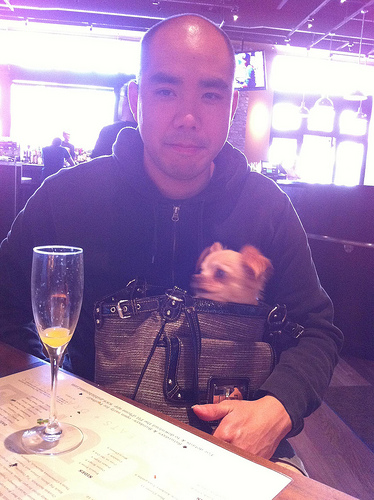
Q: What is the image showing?
A: It is showing a restaurant.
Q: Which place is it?
A: It is a restaurant.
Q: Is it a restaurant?
A: Yes, it is a restaurant.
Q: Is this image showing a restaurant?
A: Yes, it is showing a restaurant.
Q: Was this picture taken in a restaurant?
A: Yes, it was taken in a restaurant.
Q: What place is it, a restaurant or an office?
A: It is a restaurant.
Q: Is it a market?
A: No, it is a restaurant.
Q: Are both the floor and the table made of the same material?
A: Yes, both the floor and the table are made of wood.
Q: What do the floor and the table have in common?
A: The material, both the floor and the table are wooden.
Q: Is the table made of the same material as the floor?
A: Yes, both the table and the floor are made of wood.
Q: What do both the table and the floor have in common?
A: The material, both the table and the floor are wooden.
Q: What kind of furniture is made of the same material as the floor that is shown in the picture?
A: The table is made of the same material as the floor.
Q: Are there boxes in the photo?
A: No, there are no boxes.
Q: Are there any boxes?
A: No, there are no boxes.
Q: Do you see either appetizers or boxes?
A: No, there are no boxes or appetizers.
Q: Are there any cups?
A: No, there are no cups.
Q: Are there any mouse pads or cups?
A: No, there are no cups or mouse pads.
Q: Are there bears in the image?
A: No, there are no bears.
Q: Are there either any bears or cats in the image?
A: No, there are no bears or cats.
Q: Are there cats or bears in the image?
A: No, there are no bears or cats.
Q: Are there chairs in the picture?
A: No, there are no chairs.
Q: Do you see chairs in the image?
A: No, there are no chairs.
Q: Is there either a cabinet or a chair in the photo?
A: No, there are no chairs or cabinets.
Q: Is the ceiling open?
A: Yes, the ceiling is open.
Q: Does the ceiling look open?
A: Yes, the ceiling is open.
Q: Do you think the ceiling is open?
A: Yes, the ceiling is open.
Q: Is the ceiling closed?
A: No, the ceiling is open.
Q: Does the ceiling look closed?
A: No, the ceiling is open.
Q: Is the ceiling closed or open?
A: The ceiling is open.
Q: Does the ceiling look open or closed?
A: The ceiling is open.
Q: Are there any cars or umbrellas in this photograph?
A: No, there are no umbrellas or cars.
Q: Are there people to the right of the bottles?
A: Yes, there are people to the right of the bottles.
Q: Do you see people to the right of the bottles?
A: Yes, there are people to the right of the bottles.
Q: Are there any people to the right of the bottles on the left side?
A: Yes, there are people to the right of the bottles.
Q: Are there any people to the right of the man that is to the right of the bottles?
A: Yes, there are people to the right of the man.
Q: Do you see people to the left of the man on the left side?
A: No, the people are to the right of the man.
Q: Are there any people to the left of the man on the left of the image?
A: No, the people are to the right of the man.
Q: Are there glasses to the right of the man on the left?
A: No, there are people to the right of the man.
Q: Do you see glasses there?
A: No, there are no glasses.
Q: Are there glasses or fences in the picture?
A: No, there are no glasses or fences.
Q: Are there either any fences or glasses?
A: No, there are no glasses or fences.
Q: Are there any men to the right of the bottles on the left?
A: Yes, there is a man to the right of the bottles.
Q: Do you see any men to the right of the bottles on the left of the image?
A: Yes, there is a man to the right of the bottles.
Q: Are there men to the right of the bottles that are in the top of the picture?
A: Yes, there is a man to the right of the bottles.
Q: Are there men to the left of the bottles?
A: No, the man is to the right of the bottles.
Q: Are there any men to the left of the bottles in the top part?
A: No, the man is to the right of the bottles.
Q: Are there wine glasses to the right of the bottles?
A: No, there is a man to the right of the bottles.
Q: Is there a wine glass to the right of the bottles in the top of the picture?
A: No, there is a man to the right of the bottles.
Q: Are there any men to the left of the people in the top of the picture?
A: Yes, there is a man to the left of the people.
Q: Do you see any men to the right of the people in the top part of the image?
A: No, the man is to the left of the people.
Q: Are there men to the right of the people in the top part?
A: No, the man is to the left of the people.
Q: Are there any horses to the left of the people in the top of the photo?
A: No, there is a man to the left of the people.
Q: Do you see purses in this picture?
A: Yes, there is a purse.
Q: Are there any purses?
A: Yes, there is a purse.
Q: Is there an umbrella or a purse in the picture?
A: Yes, there is a purse.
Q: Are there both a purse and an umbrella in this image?
A: No, there is a purse but no umbrellas.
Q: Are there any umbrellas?
A: No, there are no umbrellas.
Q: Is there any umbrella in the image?
A: No, there are no umbrellas.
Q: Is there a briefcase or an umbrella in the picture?
A: No, there are no umbrellas or briefcases.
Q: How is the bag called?
A: The bag is a purse.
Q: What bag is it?
A: The bag is a purse.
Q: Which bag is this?
A: That is a purse.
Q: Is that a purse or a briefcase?
A: That is a purse.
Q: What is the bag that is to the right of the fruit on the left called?
A: The bag is a purse.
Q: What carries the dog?
A: The purse carries the dog.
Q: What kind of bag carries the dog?
A: The bag is a purse.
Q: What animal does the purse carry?
A: The purse carries a dog.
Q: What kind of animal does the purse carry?
A: The purse carries a dog.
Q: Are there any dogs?
A: Yes, there is a dog.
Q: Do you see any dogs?
A: Yes, there is a dog.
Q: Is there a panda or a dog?
A: Yes, there is a dog.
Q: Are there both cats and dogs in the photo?
A: No, there is a dog but no cats.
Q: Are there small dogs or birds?
A: Yes, there is a small dog.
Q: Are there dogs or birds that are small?
A: Yes, the dog is small.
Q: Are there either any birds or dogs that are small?
A: Yes, the dog is small.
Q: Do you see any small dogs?
A: Yes, there is a small dog.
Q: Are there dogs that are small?
A: Yes, there is a dog that is small.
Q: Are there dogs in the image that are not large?
A: Yes, there is a small dog.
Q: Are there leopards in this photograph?
A: No, there are no leopards.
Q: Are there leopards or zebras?
A: No, there are no leopards or zebras.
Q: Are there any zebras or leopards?
A: No, there are no leopards or zebras.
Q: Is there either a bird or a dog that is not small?
A: No, there is a dog but it is small.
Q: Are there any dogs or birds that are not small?
A: No, there is a dog but it is small.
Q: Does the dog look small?
A: Yes, the dog is small.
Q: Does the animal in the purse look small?
A: Yes, the dog is small.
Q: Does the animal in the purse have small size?
A: Yes, the dog is small.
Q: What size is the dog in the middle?
A: The dog is small.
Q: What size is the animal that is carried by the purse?
A: The dog is small.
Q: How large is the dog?
A: The dog is small.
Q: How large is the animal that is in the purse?
A: The dog is small.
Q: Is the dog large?
A: No, the dog is small.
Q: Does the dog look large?
A: No, the dog is small.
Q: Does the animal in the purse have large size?
A: No, the dog is small.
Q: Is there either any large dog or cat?
A: No, there is a dog but it is small.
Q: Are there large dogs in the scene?
A: No, there is a dog but it is small.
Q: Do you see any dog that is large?
A: No, there is a dog but it is small.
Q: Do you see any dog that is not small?
A: No, there is a dog but it is small.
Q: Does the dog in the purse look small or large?
A: The dog is small.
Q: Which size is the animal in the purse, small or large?
A: The dog is small.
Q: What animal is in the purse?
A: The dog is in the purse.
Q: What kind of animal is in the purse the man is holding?
A: The animal is a dog.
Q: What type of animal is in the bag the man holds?
A: The animal is a dog.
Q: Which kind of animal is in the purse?
A: The animal is a dog.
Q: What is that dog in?
A: The dog is in the purse.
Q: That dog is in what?
A: The dog is in the purse.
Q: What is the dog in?
A: The dog is in the purse.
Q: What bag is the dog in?
A: The dog is in the purse.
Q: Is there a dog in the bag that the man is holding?
A: Yes, there is a dog in the purse.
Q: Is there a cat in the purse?
A: No, there is a dog in the purse.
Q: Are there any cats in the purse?
A: No, there is a dog in the purse.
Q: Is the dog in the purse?
A: Yes, the dog is in the purse.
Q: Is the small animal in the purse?
A: Yes, the dog is in the purse.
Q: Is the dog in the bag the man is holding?
A: Yes, the dog is in the purse.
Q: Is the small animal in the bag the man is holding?
A: Yes, the dog is in the purse.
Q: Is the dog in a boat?
A: No, the dog is in the purse.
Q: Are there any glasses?
A: No, there are no glasses.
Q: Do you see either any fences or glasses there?
A: No, there are no glasses or fences.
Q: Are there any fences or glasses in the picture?
A: No, there are no glasses or fences.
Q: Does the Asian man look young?
A: Yes, the man is young.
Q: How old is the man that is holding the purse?
A: The man is young.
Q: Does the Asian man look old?
A: No, the man is young.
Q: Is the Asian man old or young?
A: The man is young.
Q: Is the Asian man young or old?
A: The man is young.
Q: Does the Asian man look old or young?
A: The man is young.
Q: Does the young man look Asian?
A: Yes, the man is asian.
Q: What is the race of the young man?
A: The man is asian.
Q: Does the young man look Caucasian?
A: No, the man is asian.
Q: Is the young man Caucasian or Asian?
A: The man is asian.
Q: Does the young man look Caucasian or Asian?
A: The man is asian.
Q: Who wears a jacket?
A: The man wears a jacket.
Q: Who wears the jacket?
A: The man wears a jacket.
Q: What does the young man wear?
A: The man wears a jacket.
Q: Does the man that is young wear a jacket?
A: Yes, the man wears a jacket.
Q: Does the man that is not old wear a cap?
A: No, the man wears a jacket.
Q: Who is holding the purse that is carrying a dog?
A: The man is holding the purse.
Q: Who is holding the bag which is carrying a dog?
A: The man is holding the purse.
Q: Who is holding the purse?
A: The man is holding the purse.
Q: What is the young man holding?
A: The man is holding the purse.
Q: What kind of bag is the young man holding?
A: The man is holding the purse.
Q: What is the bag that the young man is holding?
A: The bag is a purse.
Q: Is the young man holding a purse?
A: Yes, the man is holding a purse.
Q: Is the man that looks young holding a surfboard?
A: No, the man is holding a purse.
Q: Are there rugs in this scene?
A: No, there are no rugs.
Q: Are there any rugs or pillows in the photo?
A: No, there are no rugs or pillows.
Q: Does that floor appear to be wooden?
A: Yes, the floor is wooden.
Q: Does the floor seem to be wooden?
A: Yes, the floor is wooden.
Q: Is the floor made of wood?
A: Yes, the floor is made of wood.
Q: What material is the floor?
A: The floor is made of wood.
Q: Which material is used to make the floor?
A: The floor is made of wood.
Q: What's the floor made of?
A: The floor is made of wood.